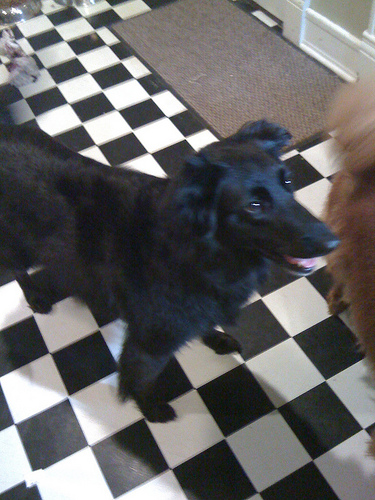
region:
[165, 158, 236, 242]
black dog's silky right ear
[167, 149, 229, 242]
black dog's glossy right ear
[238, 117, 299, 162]
black dog's silky left ear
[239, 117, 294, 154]
black dog's glossy left ear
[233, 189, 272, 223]
black dog's bright brown eye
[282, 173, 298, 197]
black dog's bright brown eye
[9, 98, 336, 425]
black dog staring attentively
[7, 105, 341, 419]
black dog stands at attention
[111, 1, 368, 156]
brown floor mat with black edges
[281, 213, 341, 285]
black dog's open mouth with pink tongue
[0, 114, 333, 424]
Black dog is standing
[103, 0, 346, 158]
Brown rug on checkered floor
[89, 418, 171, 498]
Black square next to white square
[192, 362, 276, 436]
Black square next to white square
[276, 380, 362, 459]
Black square next to white square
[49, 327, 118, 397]
Black square next to white square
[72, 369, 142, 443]
White square next to black square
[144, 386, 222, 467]
White square next to black square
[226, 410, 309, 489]
White square next to black square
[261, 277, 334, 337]
White square next to black square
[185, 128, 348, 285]
the head of a dog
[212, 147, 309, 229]
the eyes of a dog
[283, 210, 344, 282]
the nose of a dog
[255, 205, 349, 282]
the mouth of a dog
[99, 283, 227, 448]
the leg of a dog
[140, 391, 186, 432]
the paw of a dog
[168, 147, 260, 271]
the ear of a dog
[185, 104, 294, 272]
the black ears of a dog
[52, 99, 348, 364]
a all back dog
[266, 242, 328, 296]
the tongue of a dog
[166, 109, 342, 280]
head of a dog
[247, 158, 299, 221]
eye of a dog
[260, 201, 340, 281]
mouth of a dog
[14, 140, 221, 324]
body of a dog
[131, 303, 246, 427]
legs of a dog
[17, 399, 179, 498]
black and white tiles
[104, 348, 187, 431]
paw of a dog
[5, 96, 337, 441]
dog standing on floor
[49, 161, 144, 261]
fur of a dog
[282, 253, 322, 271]
tongue of a dog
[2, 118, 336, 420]
a black dog looking up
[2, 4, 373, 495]
black and white checkerboard floor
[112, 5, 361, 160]
a brown door mat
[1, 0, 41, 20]
metal dog dish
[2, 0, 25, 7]
food in the dog dish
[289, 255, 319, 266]
the dog's red tongue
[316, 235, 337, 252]
the dog's black nose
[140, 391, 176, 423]
the dog's front right paw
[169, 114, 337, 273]
the black dog's head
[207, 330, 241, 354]
the dog's front left paw